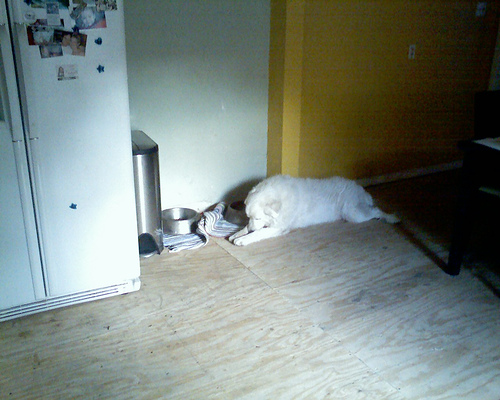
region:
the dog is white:
[219, 98, 330, 234]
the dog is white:
[226, 169, 277, 292]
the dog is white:
[258, 97, 403, 331]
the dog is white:
[194, 70, 366, 281]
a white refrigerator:
[3, 2, 135, 324]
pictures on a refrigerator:
[20, 21, 91, 61]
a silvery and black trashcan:
[131, 125, 166, 245]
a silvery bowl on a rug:
[164, 203, 194, 235]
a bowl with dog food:
[222, 194, 249, 226]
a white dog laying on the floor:
[226, 163, 396, 245]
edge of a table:
[459, 116, 498, 288]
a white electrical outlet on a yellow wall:
[402, 34, 419, 76]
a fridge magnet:
[86, 61, 111, 88]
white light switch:
[470, 0, 499, 22]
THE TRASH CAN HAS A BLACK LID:
[122, 118, 163, 161]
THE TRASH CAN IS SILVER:
[136, 119, 169, 274]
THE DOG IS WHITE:
[228, 167, 403, 248]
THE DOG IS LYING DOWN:
[223, 168, 403, 269]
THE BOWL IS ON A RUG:
[158, 198, 255, 252]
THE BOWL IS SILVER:
[159, 205, 199, 239]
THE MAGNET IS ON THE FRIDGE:
[94, 61, 105, 74]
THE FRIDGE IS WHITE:
[0, 32, 152, 318]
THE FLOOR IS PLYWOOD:
[1, 206, 496, 398]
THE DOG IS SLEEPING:
[225, 169, 400, 260]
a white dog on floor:
[227, 169, 384, 249]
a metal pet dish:
[159, 204, 199, 232]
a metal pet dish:
[222, 197, 249, 225]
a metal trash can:
[129, 130, 164, 257]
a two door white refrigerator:
[2, 0, 150, 330]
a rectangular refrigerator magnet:
[51, 61, 77, 81]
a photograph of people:
[52, 27, 87, 59]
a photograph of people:
[37, 39, 60, 60]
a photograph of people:
[72, 8, 105, 29]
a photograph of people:
[44, 1, 59, 21]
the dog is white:
[207, 166, 364, 288]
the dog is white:
[222, 155, 363, 396]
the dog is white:
[264, 153, 356, 311]